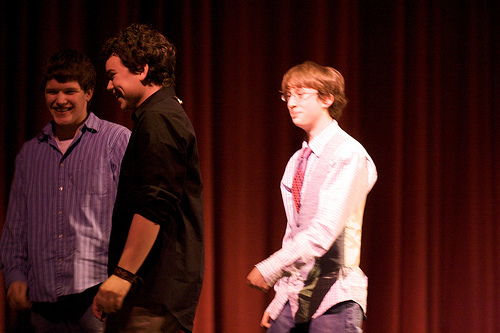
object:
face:
[281, 87, 320, 125]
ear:
[321, 91, 335, 109]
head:
[278, 63, 350, 125]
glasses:
[279, 86, 328, 101]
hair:
[39, 48, 100, 93]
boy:
[86, 26, 211, 332]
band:
[109, 262, 144, 288]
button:
[58, 185, 63, 191]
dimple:
[114, 83, 128, 96]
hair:
[281, 60, 348, 119]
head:
[40, 51, 99, 128]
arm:
[274, 154, 359, 276]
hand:
[240, 261, 279, 294]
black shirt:
[106, 85, 204, 332]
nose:
[287, 95, 297, 109]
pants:
[270, 299, 366, 333]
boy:
[243, 60, 379, 331]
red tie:
[289, 144, 311, 215]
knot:
[299, 145, 313, 159]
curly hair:
[102, 23, 177, 86]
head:
[98, 24, 177, 113]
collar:
[308, 138, 329, 158]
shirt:
[0, 110, 130, 304]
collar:
[35, 110, 103, 140]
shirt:
[255, 118, 377, 322]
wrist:
[111, 264, 135, 284]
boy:
[0, 58, 130, 333]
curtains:
[0, 0, 499, 331]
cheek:
[115, 74, 144, 98]